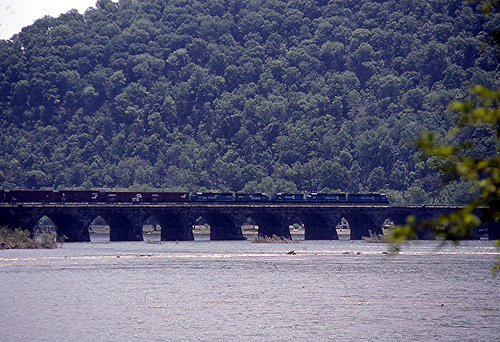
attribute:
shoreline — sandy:
[87, 217, 360, 234]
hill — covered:
[1, 2, 498, 193]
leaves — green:
[376, 78, 498, 256]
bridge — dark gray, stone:
[77, 135, 408, 310]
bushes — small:
[4, 222, 66, 249]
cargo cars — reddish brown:
[1, 184, 191, 204]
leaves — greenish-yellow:
[449, 102, 489, 236]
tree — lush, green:
[378, 136, 398, 172]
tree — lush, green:
[348, 39, 381, 80]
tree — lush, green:
[164, 44, 194, 82]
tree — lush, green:
[253, 96, 290, 130]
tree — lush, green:
[53, 67, 85, 92]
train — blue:
[1, 165, 391, 208]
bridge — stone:
[28, 184, 456, 241]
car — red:
[145, 185, 190, 201]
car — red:
[93, 186, 135, 201]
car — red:
[53, 183, 95, 202]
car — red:
[7, 186, 56, 206]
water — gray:
[3, 223, 498, 341]